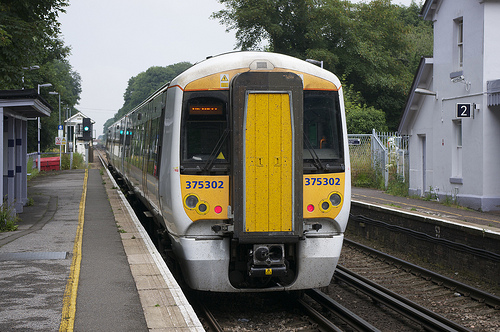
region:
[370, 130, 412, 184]
a white fence next to a building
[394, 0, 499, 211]
a white building next to the tracks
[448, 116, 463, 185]
a window in a building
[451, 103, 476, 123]
a 2 on the side of a building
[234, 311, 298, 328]
gravel between the train tracks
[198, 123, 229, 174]
a windshield wiper on a train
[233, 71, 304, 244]
a yellow connecting door on the front of a train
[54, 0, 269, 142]
a pale blue sky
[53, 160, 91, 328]
a yellow stripe on a train platform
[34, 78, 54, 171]
a lamp post on a train platform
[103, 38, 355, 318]
A train sits on the tracks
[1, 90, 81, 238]
A structure with an overhang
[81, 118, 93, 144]
A stoplight with a green light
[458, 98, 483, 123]
A platform number sign on the building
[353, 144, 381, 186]
Tall grass next to a fence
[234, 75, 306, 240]
A closed yellow door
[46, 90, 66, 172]
A tall light stand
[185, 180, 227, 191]
Numbers on the train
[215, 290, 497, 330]
Two sets of train tracks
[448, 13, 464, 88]
A second story window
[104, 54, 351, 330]
The train on tracks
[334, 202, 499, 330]
The Tracks on the right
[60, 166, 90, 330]
The long yellow road mark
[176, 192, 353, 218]
The train's head light lamps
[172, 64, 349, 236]
The train's yellow front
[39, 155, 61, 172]
A yellow container on the roadside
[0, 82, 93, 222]
The gray buildings on the left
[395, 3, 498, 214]
The gray building on the right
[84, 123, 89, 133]
The green light at the end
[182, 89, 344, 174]
The two dark front windows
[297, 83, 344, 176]
window on a train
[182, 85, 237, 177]
window on a train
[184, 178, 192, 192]
number painted on a train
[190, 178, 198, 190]
number painted on a train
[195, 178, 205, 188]
number painted on a train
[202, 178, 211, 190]
number painted on a train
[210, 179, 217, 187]
number painted on a train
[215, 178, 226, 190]
number painted on a train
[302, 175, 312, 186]
number painted on a train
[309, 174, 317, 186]
number painted on a train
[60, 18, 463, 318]
A train is moving through the city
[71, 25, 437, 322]
A train is carrying passengers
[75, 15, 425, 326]
A train is approaching a stop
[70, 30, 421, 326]
A train is going to the station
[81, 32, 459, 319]
The train is on the railroad tracks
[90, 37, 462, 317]
The train is on schedule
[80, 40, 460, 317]
The train is bringing commuters home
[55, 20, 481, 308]
The train has just picked up passengers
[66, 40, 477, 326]
The train has a powerful engine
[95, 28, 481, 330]
The train is running late today